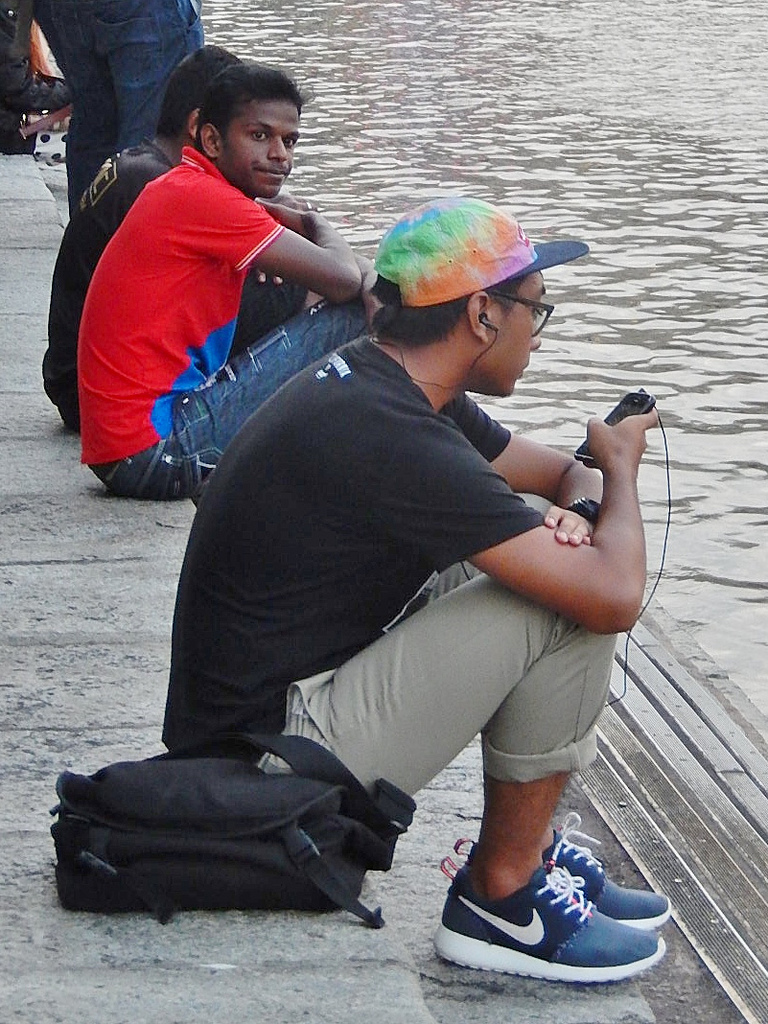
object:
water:
[184, 0, 768, 731]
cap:
[373, 197, 590, 307]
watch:
[566, 496, 601, 523]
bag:
[48, 729, 414, 927]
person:
[32, 0, 205, 221]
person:
[41, 47, 243, 431]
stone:
[4, 221, 63, 248]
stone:
[295, 985, 304, 993]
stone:
[100, 953, 125, 969]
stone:
[24, 733, 76, 774]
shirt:
[77, 145, 284, 463]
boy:
[78, 65, 379, 505]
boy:
[160, 197, 674, 985]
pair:
[435, 811, 672, 983]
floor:
[0, 151, 768, 1024]